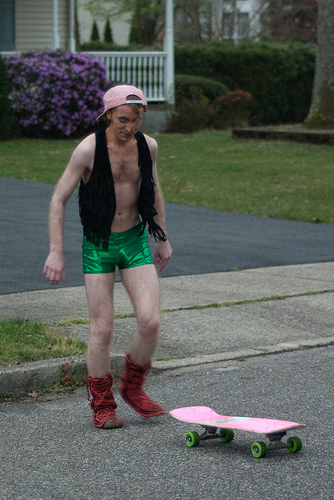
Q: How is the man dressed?
A: In green shorts and red boots.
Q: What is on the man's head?
A: Pink cap.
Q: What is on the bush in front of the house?
A: Purple flowers.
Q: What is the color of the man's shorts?
A: Green.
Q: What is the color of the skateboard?
A: Pink and green.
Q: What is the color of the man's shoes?
A: Red.